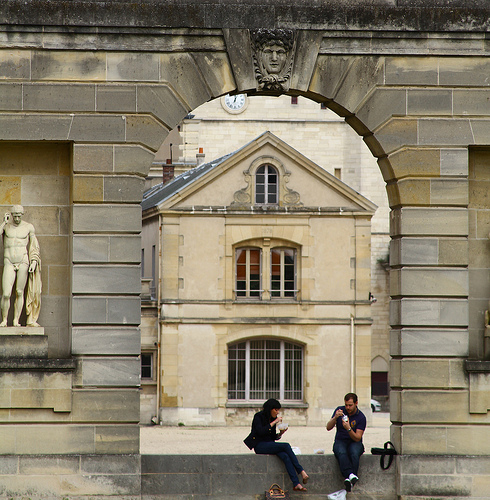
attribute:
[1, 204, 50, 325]
statue — nude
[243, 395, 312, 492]
person — eating, sitting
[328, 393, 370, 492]
person — eating, sitting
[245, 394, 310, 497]
woman — sitting, eating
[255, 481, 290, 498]
purse — brown, small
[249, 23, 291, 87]
face — carving, stone, carved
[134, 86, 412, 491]
archway — stone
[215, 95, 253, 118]
clock — built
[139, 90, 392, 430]
building — old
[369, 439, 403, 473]
bag — black, man's, vinyl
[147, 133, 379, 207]
roof — triangular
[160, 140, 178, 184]
chimney — red, brick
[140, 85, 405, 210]
arch — large, round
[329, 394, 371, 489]
man — sitting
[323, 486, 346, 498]
bag — plastic, white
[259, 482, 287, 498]
handbag — tan, brown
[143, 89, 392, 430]
face — building's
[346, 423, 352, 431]
wrist — man's